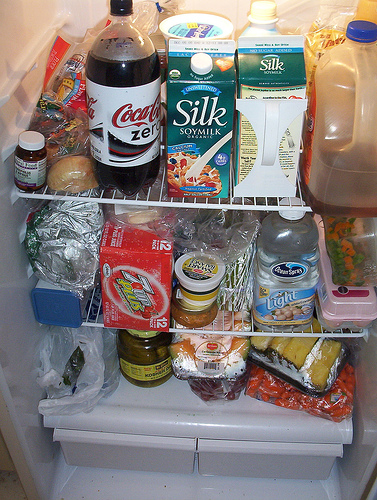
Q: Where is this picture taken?
A: A kitchen.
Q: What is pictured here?
A: A refrigerator.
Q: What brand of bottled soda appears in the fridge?
A: Coca-Cola Zero.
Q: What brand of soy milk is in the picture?
A: Silk.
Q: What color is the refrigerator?
A: White.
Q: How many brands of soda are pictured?
A: Two.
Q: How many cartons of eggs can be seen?
A: One.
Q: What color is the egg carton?
A: Pink.